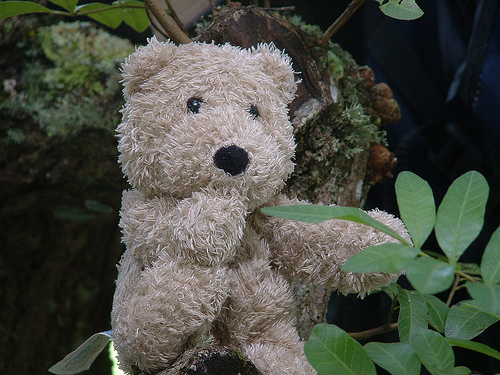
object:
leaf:
[393, 170, 436, 245]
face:
[116, 35, 297, 205]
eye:
[185, 95, 205, 115]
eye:
[248, 105, 260, 119]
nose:
[213, 144, 251, 176]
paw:
[185, 188, 252, 265]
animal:
[109, 32, 409, 375]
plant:
[257, 172, 498, 374]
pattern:
[381, 24, 483, 172]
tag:
[47, 327, 144, 374]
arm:
[143, 187, 250, 265]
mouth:
[208, 179, 259, 209]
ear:
[119, 35, 176, 85]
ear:
[252, 39, 302, 93]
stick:
[315, 0, 381, 41]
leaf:
[257, 203, 409, 247]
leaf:
[341, 241, 418, 274]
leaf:
[433, 170, 490, 264]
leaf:
[397, 285, 430, 344]